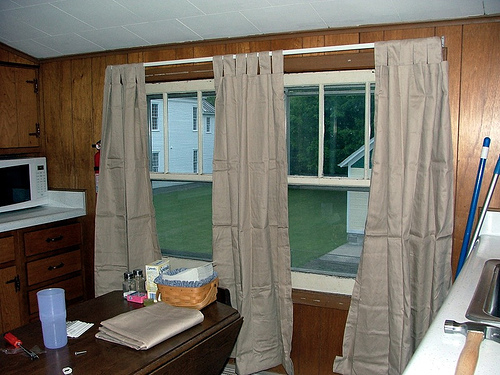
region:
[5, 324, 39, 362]
a screwdriver on a table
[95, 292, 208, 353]
a sheet on a table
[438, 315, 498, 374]
a hammer on a counter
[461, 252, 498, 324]
a kitchen sink next to a hammer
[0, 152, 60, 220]
a white microwave on a counter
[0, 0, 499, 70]
white tile on a ceiling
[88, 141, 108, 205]
a fire extinguisher on the wall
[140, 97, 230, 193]
a white house outside the window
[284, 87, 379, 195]
green trees outside the window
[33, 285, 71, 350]
a cup on the table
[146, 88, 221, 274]
window is open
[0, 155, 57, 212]
white microwave on the counter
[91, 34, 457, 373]
curtains on the window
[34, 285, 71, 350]
pale blue glass on the table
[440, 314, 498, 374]
hammer laying on the counter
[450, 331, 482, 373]
wooden handle of the hammer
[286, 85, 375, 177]
white lines on the window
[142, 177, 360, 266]
green grass on the ground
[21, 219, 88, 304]
row of three drawers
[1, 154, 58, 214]
microwave on the counter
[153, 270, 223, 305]
basket of napkins on the table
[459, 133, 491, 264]
handles leaning against the counter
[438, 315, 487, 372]
hammer laying on the counter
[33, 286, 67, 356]
plastic cup sitting on the table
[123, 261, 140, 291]
salt and pepper shaker on the table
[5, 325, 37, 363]
screw driver on the table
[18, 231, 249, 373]
dining table is dark brown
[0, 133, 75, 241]
white microwave on counter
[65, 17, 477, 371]
tan curtains hanging up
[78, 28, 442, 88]
white curtain rod above window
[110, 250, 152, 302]
salt and pepper shaker on table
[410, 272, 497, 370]
hammer on top of counter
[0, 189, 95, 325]
brown lower cabinets and drawers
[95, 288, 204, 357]
white sheet on the table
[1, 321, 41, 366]
screw driver on the table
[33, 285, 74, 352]
plastic cup on the table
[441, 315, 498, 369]
hammer on the table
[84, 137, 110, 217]
fire extinguisher on the wall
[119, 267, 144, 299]
salt shaker on the table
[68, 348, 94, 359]
nails on the table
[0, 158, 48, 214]
A white microwave with black window.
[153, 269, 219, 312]
Brown woven basket with blue lining.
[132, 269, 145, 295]
Black salt shaker on a table.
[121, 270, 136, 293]
Clear salt shaker with silver lid.